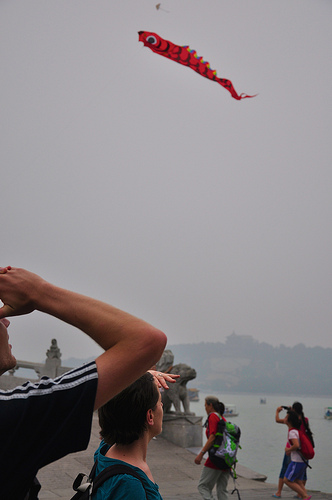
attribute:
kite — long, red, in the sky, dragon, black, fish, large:
[138, 30, 258, 101]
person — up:
[69, 370, 181, 499]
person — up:
[2, 266, 168, 498]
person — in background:
[195, 396, 228, 499]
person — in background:
[217, 402, 226, 412]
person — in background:
[283, 414, 311, 500]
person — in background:
[276, 402, 307, 500]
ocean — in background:
[173, 391, 332, 494]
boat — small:
[225, 404, 239, 418]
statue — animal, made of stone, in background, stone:
[149, 349, 202, 446]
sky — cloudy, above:
[0, 0, 331, 365]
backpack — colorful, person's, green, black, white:
[210, 420, 241, 467]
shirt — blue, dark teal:
[95, 438, 162, 499]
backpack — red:
[299, 430, 314, 461]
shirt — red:
[204, 413, 226, 470]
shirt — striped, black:
[0, 360, 98, 499]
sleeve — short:
[0, 360, 98, 470]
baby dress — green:
[219, 421, 240, 467]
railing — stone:
[1, 339, 77, 389]